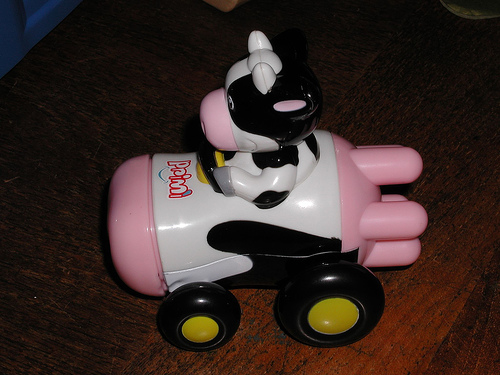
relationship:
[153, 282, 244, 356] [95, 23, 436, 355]
tire of car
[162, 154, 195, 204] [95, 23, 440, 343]
writing on car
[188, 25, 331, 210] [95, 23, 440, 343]
cow of car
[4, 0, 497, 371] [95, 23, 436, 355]
surface below car